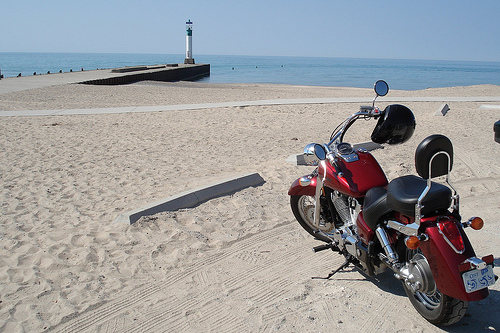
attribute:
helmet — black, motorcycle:
[369, 103, 414, 145]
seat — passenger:
[347, 131, 465, 227]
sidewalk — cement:
[21, 76, 359, 130]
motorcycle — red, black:
[280, 79, 494, 324]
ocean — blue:
[3, 52, 499, 97]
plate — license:
[459, 268, 496, 294]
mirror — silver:
[369, 78, 391, 102]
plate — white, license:
[459, 265, 497, 295]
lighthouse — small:
[184, 4, 206, 64]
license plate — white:
[457, 258, 499, 295]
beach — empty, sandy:
[6, 95, 290, 332]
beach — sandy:
[187, 227, 291, 263]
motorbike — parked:
[282, 78, 482, 330]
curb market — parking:
[123, 170, 268, 225]